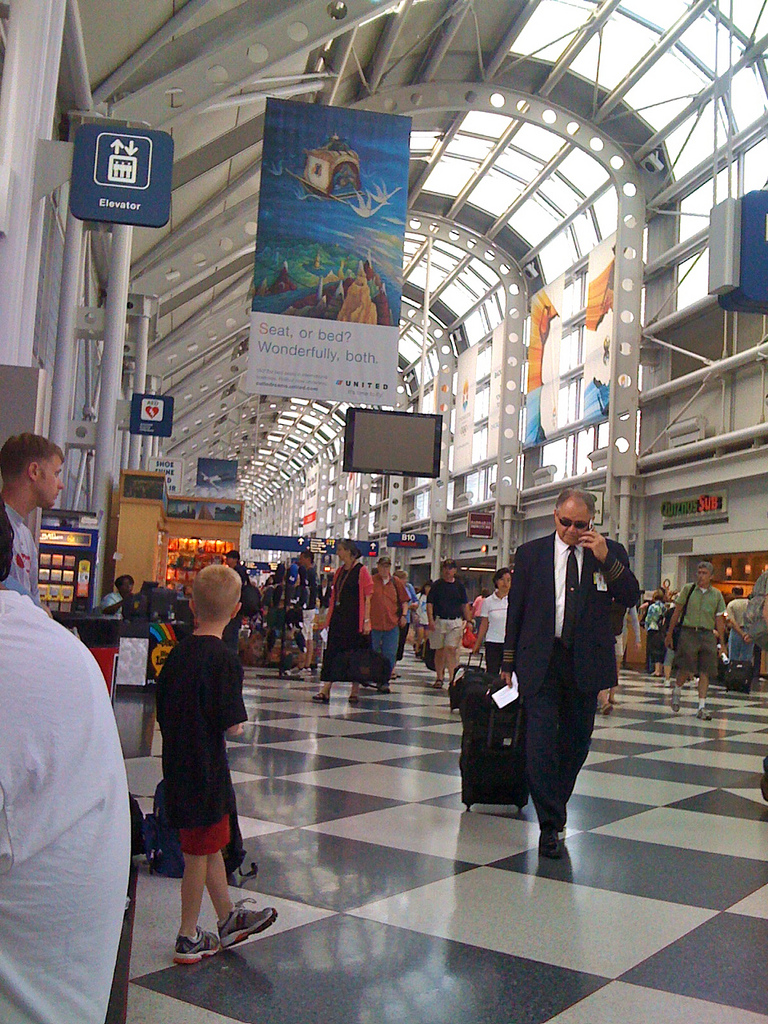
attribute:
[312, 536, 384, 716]
woman — grey haired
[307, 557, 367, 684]
dress — black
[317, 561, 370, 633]
coat — pink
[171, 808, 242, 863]
shorts — red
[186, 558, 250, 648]
head — shaved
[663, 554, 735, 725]
man — grey haired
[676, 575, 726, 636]
shirt — green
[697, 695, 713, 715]
socks — white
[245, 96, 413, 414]
banner — large, rectangle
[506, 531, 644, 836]
suit — navy blue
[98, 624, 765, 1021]
floor — black, white, checkered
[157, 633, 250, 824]
shirt — black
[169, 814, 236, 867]
shorts — red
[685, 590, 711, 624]
shirt — green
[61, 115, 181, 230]
sign — blue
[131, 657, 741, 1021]
floor — long, checkered, black, white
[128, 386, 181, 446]
sign — blue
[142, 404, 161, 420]
heart — red